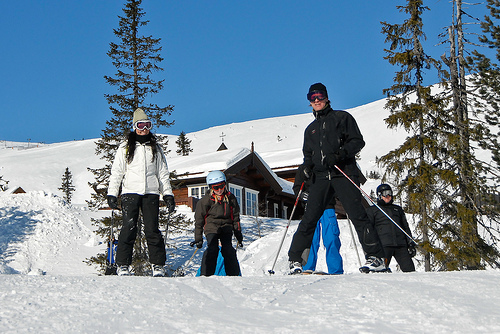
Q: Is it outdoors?
A: Yes, it is outdoors.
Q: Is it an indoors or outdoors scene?
A: It is outdoors.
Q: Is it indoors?
A: No, it is outdoors.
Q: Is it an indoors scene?
A: No, it is outdoors.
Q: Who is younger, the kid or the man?
A: The kid is younger than the man.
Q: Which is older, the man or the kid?
A: The man is older than the kid.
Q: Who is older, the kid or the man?
A: The man is older than the kid.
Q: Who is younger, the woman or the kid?
A: The kid is younger than the woman.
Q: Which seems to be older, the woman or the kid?
A: The woman is older than the kid.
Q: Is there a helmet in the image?
A: Yes, there is a helmet.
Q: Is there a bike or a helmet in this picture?
A: Yes, there is a helmet.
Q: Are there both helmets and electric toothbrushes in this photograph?
A: No, there is a helmet but no electric toothbrushes.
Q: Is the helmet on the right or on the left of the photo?
A: The helmet is on the left of the image.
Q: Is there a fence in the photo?
A: No, there are no fences.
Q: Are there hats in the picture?
A: Yes, there is a hat.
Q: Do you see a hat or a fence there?
A: Yes, there is a hat.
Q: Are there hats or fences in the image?
A: Yes, there is a hat.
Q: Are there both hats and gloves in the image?
A: Yes, there are both a hat and gloves.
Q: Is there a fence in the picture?
A: No, there are no fences.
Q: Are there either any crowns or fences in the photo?
A: No, there are no fences or crowns.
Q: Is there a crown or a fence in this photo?
A: No, there are no fences or crowns.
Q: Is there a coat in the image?
A: Yes, there is a coat.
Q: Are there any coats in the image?
A: Yes, there is a coat.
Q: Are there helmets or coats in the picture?
A: Yes, there is a coat.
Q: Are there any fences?
A: No, there are no fences.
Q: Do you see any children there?
A: Yes, there is a child.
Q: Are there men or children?
A: Yes, there is a child.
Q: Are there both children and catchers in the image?
A: No, there is a child but no catchers.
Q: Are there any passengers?
A: No, there are no passengers.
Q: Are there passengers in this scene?
A: No, there are no passengers.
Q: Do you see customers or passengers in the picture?
A: No, there are no passengers or customers.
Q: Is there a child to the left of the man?
A: Yes, there is a child to the left of the man.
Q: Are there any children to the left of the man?
A: Yes, there is a child to the left of the man.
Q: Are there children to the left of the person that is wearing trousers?
A: Yes, there is a child to the left of the man.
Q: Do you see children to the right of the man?
A: No, the child is to the left of the man.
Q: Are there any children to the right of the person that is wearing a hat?
A: No, the child is to the left of the man.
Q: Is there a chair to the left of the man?
A: No, there is a child to the left of the man.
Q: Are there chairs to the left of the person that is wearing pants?
A: No, there is a child to the left of the man.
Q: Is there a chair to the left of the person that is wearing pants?
A: No, there is a child to the left of the man.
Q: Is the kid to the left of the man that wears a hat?
A: Yes, the kid is to the left of the man.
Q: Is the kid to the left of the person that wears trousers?
A: Yes, the kid is to the left of the man.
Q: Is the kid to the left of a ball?
A: No, the kid is to the left of the man.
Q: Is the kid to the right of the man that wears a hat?
A: No, the kid is to the left of the man.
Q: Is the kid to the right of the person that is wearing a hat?
A: No, the kid is to the left of the man.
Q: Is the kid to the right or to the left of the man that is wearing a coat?
A: The kid is to the left of the man.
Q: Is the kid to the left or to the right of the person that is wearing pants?
A: The kid is to the left of the man.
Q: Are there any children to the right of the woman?
A: Yes, there is a child to the right of the woman.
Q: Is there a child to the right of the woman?
A: Yes, there is a child to the right of the woman.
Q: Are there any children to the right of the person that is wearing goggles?
A: Yes, there is a child to the right of the woman.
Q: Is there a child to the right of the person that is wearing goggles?
A: Yes, there is a child to the right of the woman.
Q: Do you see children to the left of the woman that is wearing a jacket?
A: No, the child is to the right of the woman.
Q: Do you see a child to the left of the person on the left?
A: No, the child is to the right of the woman.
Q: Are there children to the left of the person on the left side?
A: No, the child is to the right of the woman.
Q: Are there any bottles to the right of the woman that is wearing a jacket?
A: No, there is a child to the right of the woman.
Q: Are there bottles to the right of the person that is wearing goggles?
A: No, there is a child to the right of the woman.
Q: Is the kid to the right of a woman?
A: Yes, the kid is to the right of a woman.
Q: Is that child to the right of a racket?
A: No, the child is to the right of a woman.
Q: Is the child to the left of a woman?
A: No, the child is to the right of a woman.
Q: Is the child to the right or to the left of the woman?
A: The child is to the right of the woman.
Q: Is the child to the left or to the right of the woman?
A: The child is to the right of the woman.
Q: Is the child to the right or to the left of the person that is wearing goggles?
A: The child is to the right of the woman.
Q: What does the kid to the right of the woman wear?
A: The child wears a jacket.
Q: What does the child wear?
A: The child wears a jacket.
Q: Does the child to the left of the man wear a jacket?
A: Yes, the child wears a jacket.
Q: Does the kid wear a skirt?
A: No, the kid wears a jacket.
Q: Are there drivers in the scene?
A: No, there are no drivers.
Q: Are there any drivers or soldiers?
A: No, there are no drivers or soldiers.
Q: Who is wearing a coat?
A: The man is wearing a coat.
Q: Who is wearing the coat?
A: The man is wearing a coat.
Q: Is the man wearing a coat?
A: Yes, the man is wearing a coat.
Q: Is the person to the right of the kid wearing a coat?
A: Yes, the man is wearing a coat.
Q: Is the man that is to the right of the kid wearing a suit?
A: No, the man is wearing a coat.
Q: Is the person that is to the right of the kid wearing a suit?
A: No, the man is wearing a coat.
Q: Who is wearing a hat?
A: The man is wearing a hat.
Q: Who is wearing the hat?
A: The man is wearing a hat.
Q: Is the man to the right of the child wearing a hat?
A: Yes, the man is wearing a hat.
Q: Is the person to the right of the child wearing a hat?
A: Yes, the man is wearing a hat.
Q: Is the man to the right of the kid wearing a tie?
A: No, the man is wearing a hat.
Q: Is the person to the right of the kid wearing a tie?
A: No, the man is wearing a hat.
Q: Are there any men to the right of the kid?
A: Yes, there is a man to the right of the kid.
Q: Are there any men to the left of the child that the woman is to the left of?
A: No, the man is to the right of the child.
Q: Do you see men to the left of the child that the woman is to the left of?
A: No, the man is to the right of the child.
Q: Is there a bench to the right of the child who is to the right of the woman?
A: No, there is a man to the right of the child.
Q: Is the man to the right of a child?
A: Yes, the man is to the right of a child.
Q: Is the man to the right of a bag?
A: No, the man is to the right of a child.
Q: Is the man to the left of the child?
A: No, the man is to the right of the child.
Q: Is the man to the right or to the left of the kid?
A: The man is to the right of the kid.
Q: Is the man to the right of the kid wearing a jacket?
A: Yes, the man is wearing a jacket.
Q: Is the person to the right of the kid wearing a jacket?
A: Yes, the man is wearing a jacket.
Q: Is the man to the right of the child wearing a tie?
A: No, the man is wearing a jacket.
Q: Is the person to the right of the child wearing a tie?
A: No, the man is wearing a jacket.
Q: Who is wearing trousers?
A: The man is wearing trousers.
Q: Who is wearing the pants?
A: The man is wearing trousers.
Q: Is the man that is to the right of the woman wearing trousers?
A: Yes, the man is wearing trousers.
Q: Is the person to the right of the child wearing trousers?
A: Yes, the man is wearing trousers.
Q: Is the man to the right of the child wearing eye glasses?
A: No, the man is wearing trousers.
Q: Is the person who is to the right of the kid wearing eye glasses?
A: No, the man is wearing trousers.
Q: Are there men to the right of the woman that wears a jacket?
A: Yes, there is a man to the right of the woman.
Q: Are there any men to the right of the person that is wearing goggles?
A: Yes, there is a man to the right of the woman.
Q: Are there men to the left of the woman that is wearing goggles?
A: No, the man is to the right of the woman.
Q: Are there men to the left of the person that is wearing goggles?
A: No, the man is to the right of the woman.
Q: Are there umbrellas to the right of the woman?
A: No, there is a man to the right of the woman.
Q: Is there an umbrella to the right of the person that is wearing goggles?
A: No, there is a man to the right of the woman.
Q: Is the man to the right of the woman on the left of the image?
A: Yes, the man is to the right of the woman.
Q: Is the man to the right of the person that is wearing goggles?
A: Yes, the man is to the right of the woman.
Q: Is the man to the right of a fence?
A: No, the man is to the right of the woman.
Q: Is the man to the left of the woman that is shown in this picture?
A: No, the man is to the right of the woman.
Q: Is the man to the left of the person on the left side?
A: No, the man is to the right of the woman.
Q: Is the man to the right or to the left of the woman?
A: The man is to the right of the woman.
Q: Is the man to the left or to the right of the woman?
A: The man is to the right of the woman.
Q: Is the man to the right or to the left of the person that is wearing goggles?
A: The man is to the right of the woman.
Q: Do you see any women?
A: Yes, there is a woman.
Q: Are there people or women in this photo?
A: Yes, there is a woman.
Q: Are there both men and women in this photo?
A: Yes, there are both a woman and a man.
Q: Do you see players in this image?
A: No, there are no players.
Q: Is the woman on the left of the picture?
A: Yes, the woman is on the left of the image.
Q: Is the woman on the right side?
A: No, the woman is on the left of the image.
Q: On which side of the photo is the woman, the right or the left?
A: The woman is on the left of the image.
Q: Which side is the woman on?
A: The woman is on the left of the image.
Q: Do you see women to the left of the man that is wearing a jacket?
A: Yes, there is a woman to the left of the man.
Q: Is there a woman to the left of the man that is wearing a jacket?
A: Yes, there is a woman to the left of the man.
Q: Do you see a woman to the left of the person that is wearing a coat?
A: Yes, there is a woman to the left of the man.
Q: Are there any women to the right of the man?
A: No, the woman is to the left of the man.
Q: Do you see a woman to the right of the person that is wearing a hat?
A: No, the woman is to the left of the man.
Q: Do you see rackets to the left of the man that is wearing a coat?
A: No, there is a woman to the left of the man.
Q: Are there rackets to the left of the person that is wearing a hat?
A: No, there is a woman to the left of the man.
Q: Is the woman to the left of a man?
A: Yes, the woman is to the left of a man.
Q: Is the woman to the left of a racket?
A: No, the woman is to the left of a man.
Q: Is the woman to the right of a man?
A: No, the woman is to the left of a man.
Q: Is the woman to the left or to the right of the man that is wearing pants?
A: The woman is to the left of the man.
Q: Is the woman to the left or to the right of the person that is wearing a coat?
A: The woman is to the left of the man.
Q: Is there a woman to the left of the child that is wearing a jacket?
A: Yes, there is a woman to the left of the kid.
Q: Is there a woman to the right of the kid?
A: No, the woman is to the left of the kid.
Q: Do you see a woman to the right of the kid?
A: No, the woman is to the left of the kid.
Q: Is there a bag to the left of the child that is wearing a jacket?
A: No, there is a woman to the left of the child.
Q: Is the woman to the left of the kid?
A: Yes, the woman is to the left of the kid.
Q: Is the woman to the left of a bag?
A: No, the woman is to the left of the kid.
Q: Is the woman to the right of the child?
A: No, the woman is to the left of the child.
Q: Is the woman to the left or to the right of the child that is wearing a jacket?
A: The woman is to the left of the kid.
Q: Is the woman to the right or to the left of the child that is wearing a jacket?
A: The woman is to the left of the kid.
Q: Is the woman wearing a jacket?
A: Yes, the woman is wearing a jacket.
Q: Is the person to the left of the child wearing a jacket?
A: Yes, the woman is wearing a jacket.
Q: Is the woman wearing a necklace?
A: No, the woman is wearing a jacket.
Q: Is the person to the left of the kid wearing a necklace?
A: No, the woman is wearing a jacket.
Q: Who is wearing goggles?
A: The woman is wearing goggles.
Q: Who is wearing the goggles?
A: The woman is wearing goggles.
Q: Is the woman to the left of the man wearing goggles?
A: Yes, the woman is wearing goggles.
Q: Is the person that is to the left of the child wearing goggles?
A: Yes, the woman is wearing goggles.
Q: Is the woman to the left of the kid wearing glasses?
A: No, the woman is wearing goggles.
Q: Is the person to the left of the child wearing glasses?
A: No, the woman is wearing goggles.